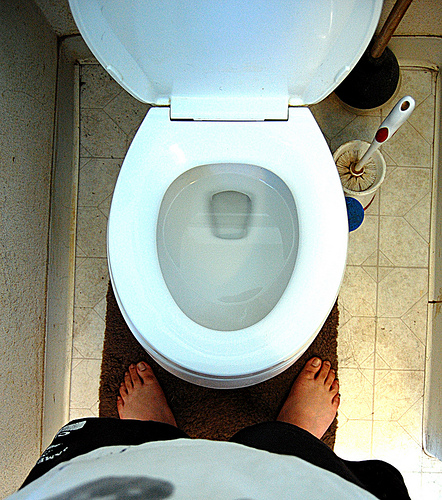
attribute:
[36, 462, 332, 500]
shirt — white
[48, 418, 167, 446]
shorts — black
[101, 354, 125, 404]
rug — brown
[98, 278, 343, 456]
rug — brown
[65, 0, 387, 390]
toilet — clean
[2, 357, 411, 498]
person — barefoot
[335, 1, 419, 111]
plunger — black, rubber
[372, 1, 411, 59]
handle — wooden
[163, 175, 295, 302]
water — clear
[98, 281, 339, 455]
bathroom carpet — shaggy, brown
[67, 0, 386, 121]
toilet lid — shiny, white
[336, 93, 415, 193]
toilet brush — white, red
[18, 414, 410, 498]
shorts — baggy, black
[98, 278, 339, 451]
bathroom rug — brown, shaggy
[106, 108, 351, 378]
toilet seat — white, shiny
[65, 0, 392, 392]
white toilet — shiny, seat cover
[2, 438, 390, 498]
white shirt — large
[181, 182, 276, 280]
water — toilet bowl, reflective, clear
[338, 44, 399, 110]
rubber plunger — black, with a wooden handle